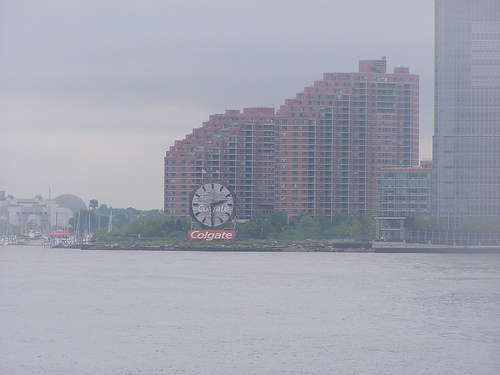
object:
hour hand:
[210, 198, 231, 205]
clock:
[189, 180, 237, 229]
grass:
[246, 235, 353, 247]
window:
[241, 148, 245, 153]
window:
[239, 198, 245, 203]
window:
[240, 173, 245, 177]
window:
[240, 149, 246, 154]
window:
[207, 167, 213, 172]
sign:
[187, 231, 233, 242]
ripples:
[275, 342, 304, 353]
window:
[239, 185, 245, 190]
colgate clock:
[186, 181, 236, 242]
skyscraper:
[432, 0, 497, 249]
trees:
[142, 212, 177, 236]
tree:
[324, 224, 356, 242]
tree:
[292, 214, 321, 241]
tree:
[240, 221, 260, 240]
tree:
[120, 222, 135, 246]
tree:
[90, 226, 110, 244]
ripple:
[130, 322, 184, 332]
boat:
[13, 230, 46, 241]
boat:
[41, 230, 74, 246]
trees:
[413, 215, 443, 245]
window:
[171, 179, 176, 183]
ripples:
[27, 262, 295, 362]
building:
[376, 1, 498, 245]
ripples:
[0, 246, 217, 372]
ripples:
[169, 320, 287, 372]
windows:
[319, 189, 325, 195]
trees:
[253, 220, 276, 241]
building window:
[245, 143, 252, 149]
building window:
[359, 94, 366, 101]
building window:
[302, 157, 307, 163]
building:
[164, 53, 421, 230]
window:
[240, 137, 246, 141]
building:
[0, 191, 122, 244]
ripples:
[308, 326, 353, 361]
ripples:
[274, 277, 366, 318]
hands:
[210, 203, 215, 228]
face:
[191, 180, 235, 228]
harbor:
[4, 236, 496, 372]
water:
[0, 242, 497, 375]